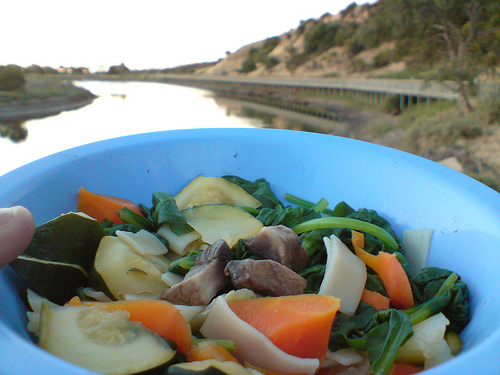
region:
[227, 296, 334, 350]
a orange slice of carrot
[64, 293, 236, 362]
a orange slice of carrot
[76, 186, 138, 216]
a orange slice of carrot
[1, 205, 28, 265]
a tip of a thumb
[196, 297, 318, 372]
a rectangluar piece of cheese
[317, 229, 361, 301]
a rectangluar piece of cheese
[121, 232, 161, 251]
a rectangluar piece of cheese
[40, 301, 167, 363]
a piece of cucumber sliced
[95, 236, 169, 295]
a piece of cucumber sliced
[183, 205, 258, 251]
a piece of cucumber sliced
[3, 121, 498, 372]
a blue bowl containing vegetables and noodles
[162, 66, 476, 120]
a long road that is next to a river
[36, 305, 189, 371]
a piece of squash in the bowl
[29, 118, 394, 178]
the top edge of the blue bowl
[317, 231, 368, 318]
a egg noodle in the bowl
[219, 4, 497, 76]
a large hill with trees and shrubs growing on it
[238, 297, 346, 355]
a large piece of carrot in the bowl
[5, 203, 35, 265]
the tip of the thumb of the person holding the bowl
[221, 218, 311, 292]
two pieces of chopped mushrooms in the bowl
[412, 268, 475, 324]
some wilted greens in the bowl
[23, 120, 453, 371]
Food in a bowl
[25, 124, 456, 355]
Food in a blue bowl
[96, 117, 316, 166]
The edge of a blue bowl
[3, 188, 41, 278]
the finger of a person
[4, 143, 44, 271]
the finger of a person holding a bowl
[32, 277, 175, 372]
A cucumber in a bowl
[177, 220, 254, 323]
A mushroom in a bowl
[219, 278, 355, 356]
Orange food in a bowl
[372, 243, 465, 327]
Cooked spinach in a bowl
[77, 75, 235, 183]
Water in the background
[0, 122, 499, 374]
a blue bowl of food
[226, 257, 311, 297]
a mushroom slice in the bowl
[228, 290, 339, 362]
a carrot slice in the bowl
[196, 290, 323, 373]
a strip of pasta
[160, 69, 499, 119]
a gray metal guard rail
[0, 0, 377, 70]
a bright gray sky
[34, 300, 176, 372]
a piece of squash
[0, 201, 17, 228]
a fingernail of a person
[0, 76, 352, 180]
a body of water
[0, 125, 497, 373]
blue bowl of food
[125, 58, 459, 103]
highway beside the river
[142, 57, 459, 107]
highway beside the canal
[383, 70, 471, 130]
nearby bridge over tributary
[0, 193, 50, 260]
the left thumb of a person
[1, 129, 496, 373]
a blue dish of food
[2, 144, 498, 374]
stir fry in a blue bowl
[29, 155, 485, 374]
stir fry in a blue dish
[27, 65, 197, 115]
a curve in the river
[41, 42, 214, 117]
a curve in the canal